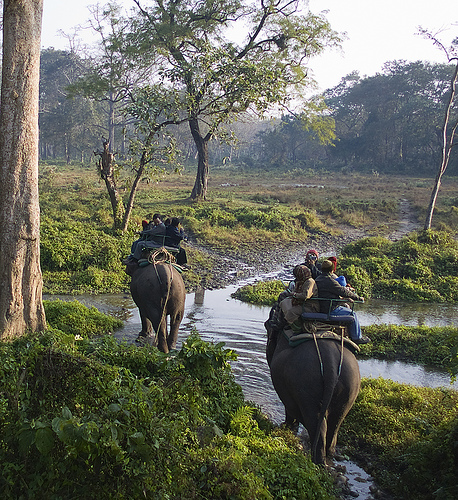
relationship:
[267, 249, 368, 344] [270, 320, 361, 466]
people riding elephant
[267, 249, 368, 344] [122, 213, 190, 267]
people riding people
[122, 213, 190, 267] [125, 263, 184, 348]
people riding elephant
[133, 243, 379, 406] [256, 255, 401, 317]
elephants carrying people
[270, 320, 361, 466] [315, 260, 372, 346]
elephant carrying people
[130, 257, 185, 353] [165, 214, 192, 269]
elephant carrying people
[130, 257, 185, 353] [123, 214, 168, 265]
elephant carrying people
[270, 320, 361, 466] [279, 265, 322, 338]
elephant carrying people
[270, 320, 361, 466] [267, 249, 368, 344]
elephant carrying people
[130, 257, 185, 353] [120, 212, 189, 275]
elephant carrying people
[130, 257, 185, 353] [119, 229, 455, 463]
elephant walking near water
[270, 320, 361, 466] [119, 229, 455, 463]
elephant walking near water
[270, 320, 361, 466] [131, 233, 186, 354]
elephant walking with elephant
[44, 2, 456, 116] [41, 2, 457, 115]
clouds in sky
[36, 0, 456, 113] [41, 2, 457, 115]
clouds in sky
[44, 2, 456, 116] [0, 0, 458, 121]
clouds in sky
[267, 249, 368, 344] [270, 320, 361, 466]
people on elephant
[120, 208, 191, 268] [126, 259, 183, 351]
people on elephant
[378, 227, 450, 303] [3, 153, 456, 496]
grass on shore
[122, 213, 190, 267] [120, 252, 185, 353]
people riding elephant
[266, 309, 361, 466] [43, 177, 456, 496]
elephant walking through water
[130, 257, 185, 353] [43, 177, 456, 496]
elephant walking through water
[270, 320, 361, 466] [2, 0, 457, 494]
elephant moving through jungle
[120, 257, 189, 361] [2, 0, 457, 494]
elephant moving through jungle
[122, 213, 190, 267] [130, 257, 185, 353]
people riding elephant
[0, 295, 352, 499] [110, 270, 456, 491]
grass near river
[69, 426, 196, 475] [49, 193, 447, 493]
grass near river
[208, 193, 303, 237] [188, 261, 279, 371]
grass near river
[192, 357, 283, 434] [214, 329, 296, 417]
grass near river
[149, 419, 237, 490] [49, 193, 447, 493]
grass near river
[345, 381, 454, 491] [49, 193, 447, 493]
grass near river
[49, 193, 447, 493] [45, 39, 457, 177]
river by trees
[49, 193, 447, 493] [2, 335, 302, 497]
river by grass